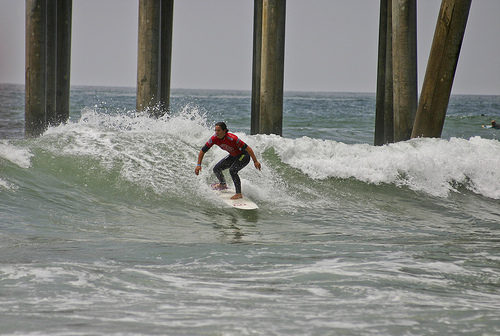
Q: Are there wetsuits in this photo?
A: Yes, there is a wetsuit.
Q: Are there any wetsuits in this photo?
A: Yes, there is a wetsuit.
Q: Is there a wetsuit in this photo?
A: Yes, there is a wetsuit.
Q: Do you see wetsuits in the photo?
A: Yes, there is a wetsuit.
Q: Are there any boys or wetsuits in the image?
A: Yes, there is a wetsuit.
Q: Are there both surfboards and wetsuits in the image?
A: Yes, there are both a wetsuit and a surfboard.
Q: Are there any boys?
A: No, there are no boys.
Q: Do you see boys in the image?
A: No, there are no boys.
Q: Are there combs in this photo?
A: No, there are no combs.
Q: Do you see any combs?
A: No, there are no combs.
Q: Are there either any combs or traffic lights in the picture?
A: No, there are no combs or traffic lights.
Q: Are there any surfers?
A: Yes, there is a surfer.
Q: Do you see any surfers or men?
A: Yes, there is a surfer.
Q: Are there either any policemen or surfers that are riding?
A: Yes, the surfer is riding.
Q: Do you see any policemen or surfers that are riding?
A: Yes, the surfer is riding.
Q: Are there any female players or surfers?
A: Yes, there is a female surfer.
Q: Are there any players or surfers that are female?
A: Yes, the surfer is female.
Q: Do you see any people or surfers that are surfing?
A: Yes, the surfer is surfing.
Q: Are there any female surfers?
A: Yes, there is a female surfer.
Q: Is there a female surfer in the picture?
A: Yes, there is a female surfer.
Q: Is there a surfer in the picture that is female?
A: Yes, there is a surfer that is female.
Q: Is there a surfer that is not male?
A: Yes, there is a female surfer.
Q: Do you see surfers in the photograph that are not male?
A: Yes, there is a female surfer.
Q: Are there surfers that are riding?
A: Yes, there is a surfer that is riding.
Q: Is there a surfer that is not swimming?
A: Yes, there is a surfer that is riding.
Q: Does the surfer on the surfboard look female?
A: Yes, the surfer is female.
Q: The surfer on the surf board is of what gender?
A: The surfer is female.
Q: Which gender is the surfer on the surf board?
A: The surfer is female.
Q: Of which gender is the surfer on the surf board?
A: The surfer is female.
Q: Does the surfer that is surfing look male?
A: No, the surfer is female.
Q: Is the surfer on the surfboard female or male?
A: The surfer is female.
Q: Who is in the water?
A: The surfer is in the water.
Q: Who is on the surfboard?
A: The surfer is on the surfboard.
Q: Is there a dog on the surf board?
A: No, there is a surfer on the surf board.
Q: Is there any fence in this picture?
A: No, there are no fences.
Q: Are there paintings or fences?
A: No, there are no fences or paintings.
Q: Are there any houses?
A: No, there are no houses.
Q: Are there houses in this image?
A: No, there are no houses.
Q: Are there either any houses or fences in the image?
A: No, there are no houses or fences.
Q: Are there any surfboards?
A: Yes, there is a surfboard.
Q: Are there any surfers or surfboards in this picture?
A: Yes, there is a surfboard.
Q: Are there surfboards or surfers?
A: Yes, there is a surfboard.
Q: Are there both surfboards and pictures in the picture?
A: No, there is a surfboard but no pictures.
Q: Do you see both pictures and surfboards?
A: No, there is a surfboard but no pictures.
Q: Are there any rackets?
A: No, there are no rackets.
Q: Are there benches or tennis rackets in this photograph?
A: No, there are no tennis rackets or benches.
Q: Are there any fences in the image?
A: No, there are no fences.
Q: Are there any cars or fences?
A: No, there are no fences or cars.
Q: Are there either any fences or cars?
A: No, there are no fences or cars.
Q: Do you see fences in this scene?
A: No, there are no fences.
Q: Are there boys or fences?
A: No, there are no fences or boys.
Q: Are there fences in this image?
A: No, there are no fences.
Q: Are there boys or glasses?
A: No, there are no boys or glasses.